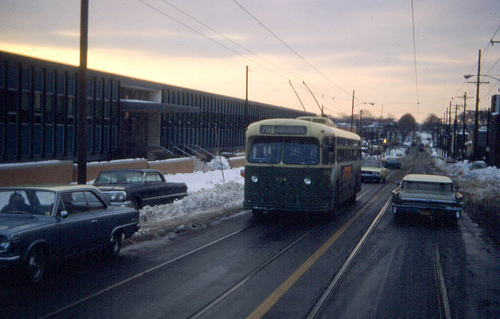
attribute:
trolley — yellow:
[243, 119, 362, 214]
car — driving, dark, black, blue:
[2, 184, 139, 284]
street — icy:
[1, 131, 499, 312]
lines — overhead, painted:
[141, 2, 390, 122]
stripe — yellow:
[252, 166, 404, 311]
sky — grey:
[1, 3, 498, 125]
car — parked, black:
[92, 170, 189, 209]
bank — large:
[451, 161, 499, 187]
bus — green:
[242, 116, 364, 215]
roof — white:
[403, 174, 452, 185]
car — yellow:
[360, 157, 387, 181]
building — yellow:
[2, 46, 317, 187]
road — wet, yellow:
[4, 130, 499, 312]